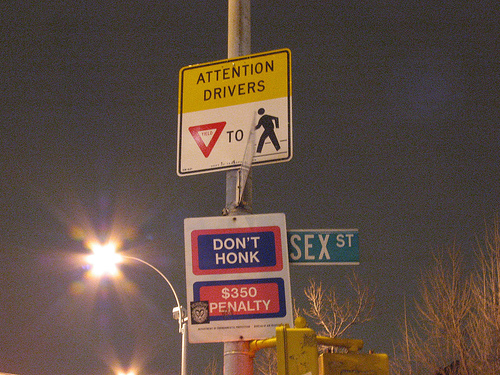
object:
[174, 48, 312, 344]
signs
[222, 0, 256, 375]
pole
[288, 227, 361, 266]
sign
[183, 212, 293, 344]
sign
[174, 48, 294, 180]
sign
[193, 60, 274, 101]
letters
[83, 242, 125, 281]
light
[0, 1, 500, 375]
sky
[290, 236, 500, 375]
branches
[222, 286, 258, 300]
dollar amount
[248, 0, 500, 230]
clouds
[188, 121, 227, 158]
yield sign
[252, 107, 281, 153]
person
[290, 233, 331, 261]
word sex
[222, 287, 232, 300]
$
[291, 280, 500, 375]
back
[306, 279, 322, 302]
part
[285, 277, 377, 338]
branch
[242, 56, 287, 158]
part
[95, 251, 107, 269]
part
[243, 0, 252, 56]
edge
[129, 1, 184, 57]
part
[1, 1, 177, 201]
cloud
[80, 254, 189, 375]
street light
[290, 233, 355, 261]
sex st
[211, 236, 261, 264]
directions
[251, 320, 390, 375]
signals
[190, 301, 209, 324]
badge